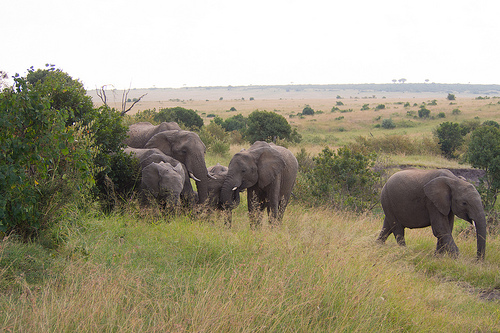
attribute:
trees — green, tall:
[389, 76, 410, 84]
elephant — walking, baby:
[378, 165, 488, 261]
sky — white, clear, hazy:
[3, 1, 499, 90]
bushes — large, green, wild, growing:
[0, 62, 131, 249]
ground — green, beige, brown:
[5, 85, 497, 332]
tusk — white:
[468, 219, 477, 228]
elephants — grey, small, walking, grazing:
[118, 115, 487, 261]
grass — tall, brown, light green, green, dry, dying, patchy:
[2, 82, 496, 332]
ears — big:
[420, 174, 466, 218]